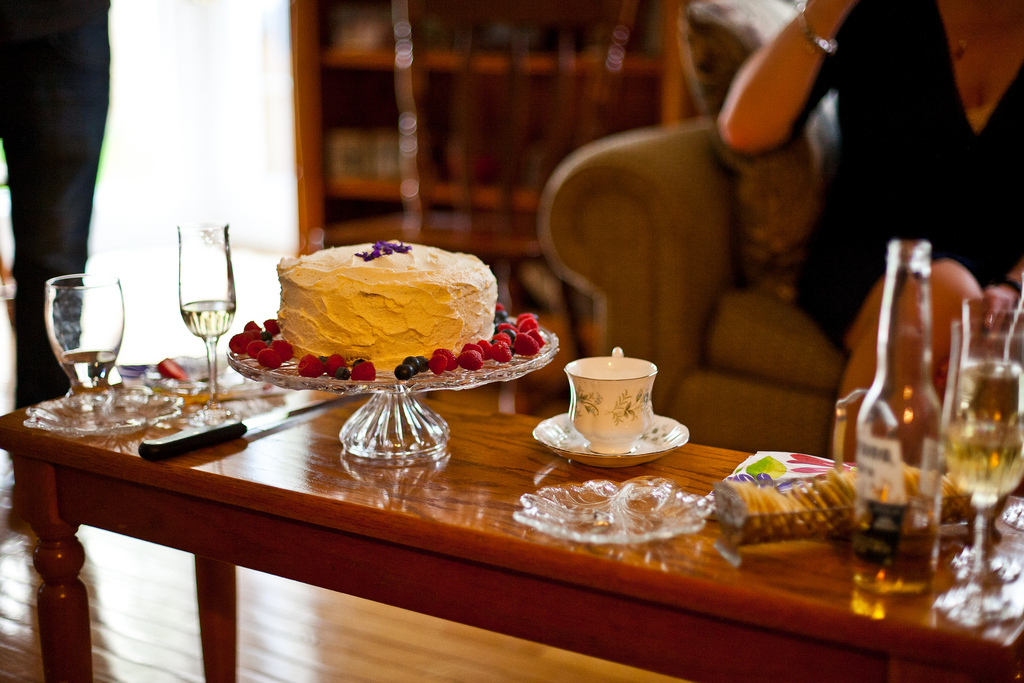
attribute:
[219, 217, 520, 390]
cake — one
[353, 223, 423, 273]
toppings — violet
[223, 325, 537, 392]
berries — some, various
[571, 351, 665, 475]
cup — white, tea, patterned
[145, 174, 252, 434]
glass — tall, clear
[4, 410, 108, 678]
foot — wooden, brown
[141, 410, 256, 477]
handle — black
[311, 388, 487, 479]
base — clear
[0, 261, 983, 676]
table — one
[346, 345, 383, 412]
raspberry — red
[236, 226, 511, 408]
cake — white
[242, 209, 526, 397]
cake — white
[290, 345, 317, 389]
raspberry — red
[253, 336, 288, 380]
raspberry — red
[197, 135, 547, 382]
cake — white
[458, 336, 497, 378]
raspberry — red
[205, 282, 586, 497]
cake stand — glass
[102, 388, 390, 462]
knife — black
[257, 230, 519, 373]
cake — white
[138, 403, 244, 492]
handle — black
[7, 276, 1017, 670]
coffee table — wooden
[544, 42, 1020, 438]
sofa — one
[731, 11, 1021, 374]
woman — one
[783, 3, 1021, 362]
dress — black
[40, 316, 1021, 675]
table — wooden, long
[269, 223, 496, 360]
cake — one, vanilla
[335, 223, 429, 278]
blueberries — some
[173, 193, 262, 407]
glass — wine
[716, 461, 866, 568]
crackers — some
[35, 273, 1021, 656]
table — one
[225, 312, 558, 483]
holder — cake, crystal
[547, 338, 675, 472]
cup — floral, tea, beige